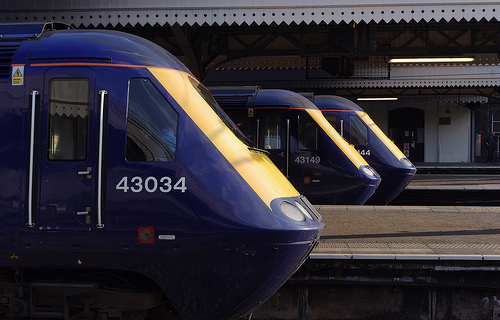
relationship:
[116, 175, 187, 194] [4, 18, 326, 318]
numbering on side of train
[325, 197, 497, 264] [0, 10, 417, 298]
platform between trains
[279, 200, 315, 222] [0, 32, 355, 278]
light in front of train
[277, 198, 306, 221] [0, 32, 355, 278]
light in front of train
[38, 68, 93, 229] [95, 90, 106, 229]
door between bar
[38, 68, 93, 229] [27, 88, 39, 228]
door between bar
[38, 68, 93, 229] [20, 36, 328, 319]
door on cockpit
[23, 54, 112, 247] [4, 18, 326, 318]
door on side of train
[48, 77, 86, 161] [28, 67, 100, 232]
window on door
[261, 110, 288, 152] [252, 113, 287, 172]
window on door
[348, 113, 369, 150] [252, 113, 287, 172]
window on door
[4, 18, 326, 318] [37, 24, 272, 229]
train has cockpit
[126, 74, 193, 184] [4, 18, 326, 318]
window on train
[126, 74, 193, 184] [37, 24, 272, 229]
window on cockpit